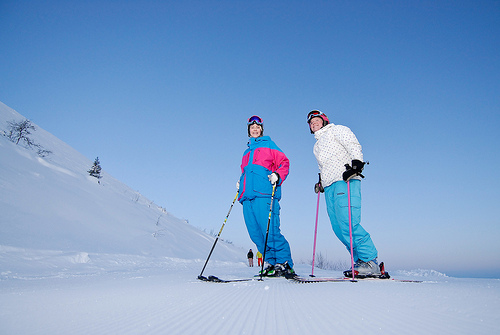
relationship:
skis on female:
[290, 263, 423, 289] [238, 116, 294, 279]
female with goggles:
[238, 116, 294, 279] [244, 108, 325, 124]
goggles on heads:
[244, 108, 325, 124] [244, 108, 333, 137]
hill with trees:
[2, 103, 259, 276] [3, 117, 104, 180]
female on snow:
[238, 116, 294, 279] [4, 104, 495, 332]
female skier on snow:
[305, 108, 389, 281] [4, 104, 495, 332]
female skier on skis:
[305, 108, 385, 277] [295, 272, 426, 283]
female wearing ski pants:
[238, 116, 294, 279] [238, 196, 293, 266]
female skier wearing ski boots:
[305, 108, 385, 277] [345, 257, 384, 278]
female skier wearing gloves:
[305, 108, 385, 277] [330, 159, 364, 172]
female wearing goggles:
[238, 116, 294, 279] [247, 115, 264, 124]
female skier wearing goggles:
[305, 108, 385, 277] [305, 109, 322, 123]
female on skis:
[238, 116, 294, 279] [194, 269, 294, 283]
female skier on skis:
[305, 108, 385, 277] [289, 271, 424, 282]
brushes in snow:
[4, 117, 54, 159] [4, 104, 495, 332]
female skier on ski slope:
[305, 108, 385, 277] [3, 105, 493, 331]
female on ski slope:
[238, 116, 294, 279] [3, 105, 493, 331]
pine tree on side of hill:
[88, 156, 103, 180] [0, 103, 261, 281]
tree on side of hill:
[1, 113, 51, 164] [0, 103, 261, 281]